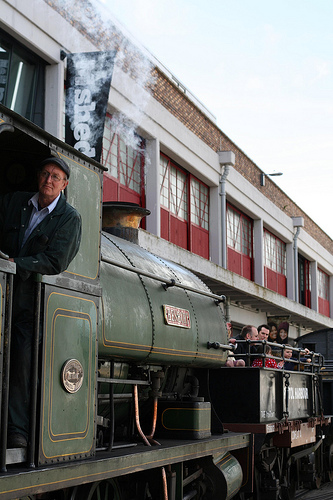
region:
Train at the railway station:
[5, 10, 328, 403]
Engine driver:
[8, 62, 320, 427]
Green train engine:
[3, 79, 322, 483]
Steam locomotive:
[1, 37, 329, 421]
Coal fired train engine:
[2, 1, 323, 422]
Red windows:
[129, 34, 329, 298]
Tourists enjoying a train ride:
[4, 101, 328, 423]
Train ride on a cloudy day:
[3, 0, 331, 406]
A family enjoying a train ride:
[2, 97, 326, 476]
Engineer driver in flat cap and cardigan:
[4, 50, 277, 419]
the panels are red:
[107, 121, 158, 218]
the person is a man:
[16, 149, 84, 291]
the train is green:
[51, 297, 281, 453]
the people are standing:
[219, 295, 328, 383]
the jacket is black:
[17, 199, 95, 286]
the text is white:
[55, 39, 121, 157]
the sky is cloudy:
[223, 16, 319, 97]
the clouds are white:
[224, 19, 321, 137]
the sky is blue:
[254, 1, 328, 116]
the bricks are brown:
[166, 85, 234, 159]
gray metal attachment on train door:
[56, 355, 88, 398]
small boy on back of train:
[284, 343, 297, 365]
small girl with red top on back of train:
[254, 346, 273, 370]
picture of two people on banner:
[271, 319, 291, 343]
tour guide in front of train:
[1, 151, 75, 481]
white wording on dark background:
[68, 52, 103, 158]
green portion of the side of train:
[107, 271, 147, 337]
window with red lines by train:
[161, 158, 192, 213]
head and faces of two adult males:
[240, 324, 279, 343]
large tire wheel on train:
[195, 456, 230, 498]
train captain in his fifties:
[1, 149, 85, 282]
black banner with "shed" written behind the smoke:
[60, 41, 128, 165]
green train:
[2, 100, 227, 485]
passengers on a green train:
[131, 247, 326, 499]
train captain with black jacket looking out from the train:
[0, 137, 80, 284]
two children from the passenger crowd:
[255, 340, 323, 373]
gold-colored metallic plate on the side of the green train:
[49, 296, 95, 453]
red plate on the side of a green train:
[158, 302, 201, 331]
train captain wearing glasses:
[11, 137, 89, 303]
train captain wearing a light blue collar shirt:
[12, 139, 84, 288]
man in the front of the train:
[2, 153, 69, 469]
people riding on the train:
[225, 317, 324, 370]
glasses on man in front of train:
[37, 168, 66, 182]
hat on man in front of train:
[39, 153, 74, 174]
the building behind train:
[110, 23, 332, 322]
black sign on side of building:
[61, 47, 123, 162]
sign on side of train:
[161, 301, 193, 327]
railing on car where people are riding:
[230, 338, 324, 371]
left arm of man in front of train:
[6, 210, 82, 277]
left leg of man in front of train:
[10, 301, 36, 447]